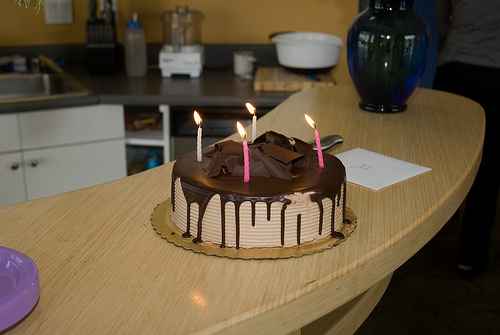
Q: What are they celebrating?
A: Birthday.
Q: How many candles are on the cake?
A: Four.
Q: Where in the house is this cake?
A: Kitchen.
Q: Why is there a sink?
A: Clean dishes.